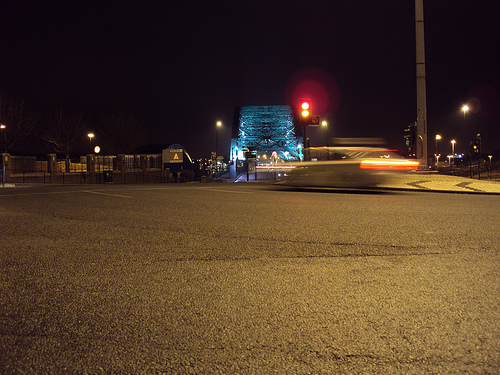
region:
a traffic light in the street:
[294, 87, 316, 129]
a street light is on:
[456, 99, 473, 129]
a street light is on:
[210, 115, 226, 133]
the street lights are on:
[82, 129, 103, 157]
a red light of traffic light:
[298, 99, 310, 109]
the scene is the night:
[1, 2, 498, 214]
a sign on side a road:
[155, 144, 188, 180]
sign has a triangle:
[157, 145, 189, 170]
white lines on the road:
[56, 174, 141, 208]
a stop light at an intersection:
[295, 95, 313, 125]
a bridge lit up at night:
[228, 103, 305, 167]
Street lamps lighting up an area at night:
[2, 103, 499, 150]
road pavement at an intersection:
[3, 178, 498, 374]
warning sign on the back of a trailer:
[170, 150, 180, 161]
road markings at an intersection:
[0, 180, 294, 200]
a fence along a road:
[2, 150, 169, 183]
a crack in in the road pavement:
[0, 328, 499, 369]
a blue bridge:
[216, 93, 316, 190]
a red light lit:
[295, 92, 317, 128]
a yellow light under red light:
[286, 94, 322, 124]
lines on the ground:
[49, 167, 294, 210]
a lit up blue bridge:
[221, 87, 330, 189]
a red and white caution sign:
[171, 150, 183, 161]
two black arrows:
[398, 164, 498, 216]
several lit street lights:
[407, 92, 493, 169]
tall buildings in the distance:
[203, 138, 231, 185]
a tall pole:
[404, 4, 431, 187]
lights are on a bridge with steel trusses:
[4, 72, 499, 199]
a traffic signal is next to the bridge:
[291, 89, 319, 184]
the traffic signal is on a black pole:
[289, 90, 321, 174]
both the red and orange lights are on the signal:
[292, 93, 319, 177]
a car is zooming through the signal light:
[266, 142, 425, 197]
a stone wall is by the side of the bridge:
[1, 147, 165, 192]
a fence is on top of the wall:
[3, 153, 163, 175]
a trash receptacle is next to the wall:
[96, 164, 119, 189]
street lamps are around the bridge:
[0, 86, 490, 161]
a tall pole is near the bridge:
[403, 3, 451, 178]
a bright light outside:
[77, 122, 97, 147]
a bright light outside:
[90, 145, 107, 169]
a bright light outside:
[1, 120, 14, 140]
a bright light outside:
[206, 111, 228, 136]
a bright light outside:
[290, 96, 313, 111]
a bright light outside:
[301, 111, 318, 122]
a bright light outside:
[318, 116, 332, 141]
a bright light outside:
[432, 127, 446, 155]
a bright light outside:
[445, 132, 461, 153]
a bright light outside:
[452, 94, 475, 123]